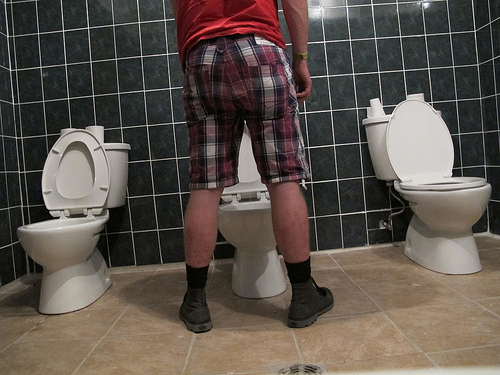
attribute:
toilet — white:
[358, 88, 495, 279]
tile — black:
[63, 30, 90, 60]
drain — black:
[273, 360, 323, 374]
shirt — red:
[173, 1, 286, 57]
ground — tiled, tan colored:
[4, 221, 498, 373]